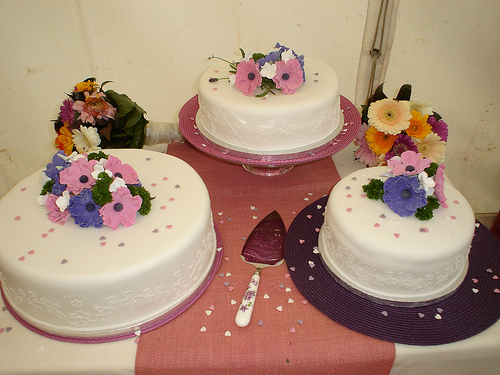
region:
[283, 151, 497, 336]
A cake on a purple place mat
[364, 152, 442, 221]
Icing flowers on a cake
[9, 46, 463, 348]
Three white cakes on a table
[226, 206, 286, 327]
A small spatula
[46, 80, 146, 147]
A bouquet of fake flowers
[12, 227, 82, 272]
Heart shaped sprinkles on a cake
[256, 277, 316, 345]
Sprinkles on the tablecloth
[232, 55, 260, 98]
A pink flower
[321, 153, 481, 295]
A white cake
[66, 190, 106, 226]
A purple flower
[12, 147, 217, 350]
A white cake with flowers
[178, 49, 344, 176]
A cake on a pink plate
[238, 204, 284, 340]
A cake server on a table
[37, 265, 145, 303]
The edge of a white cake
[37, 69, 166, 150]
A bouquet of flowers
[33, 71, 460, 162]
Two bouquets of flowers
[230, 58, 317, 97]
Two pink flowers on a cake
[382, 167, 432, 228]
A purple flower on a cake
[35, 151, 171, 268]
A bunch of flowers on a cake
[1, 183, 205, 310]
this is a cake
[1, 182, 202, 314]
the cake is white in color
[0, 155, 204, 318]
the cake is large in size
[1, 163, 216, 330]
the cake is creamy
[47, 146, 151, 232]
the cream is flower like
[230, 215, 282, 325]
this is a spoon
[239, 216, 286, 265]
the spoon is creamy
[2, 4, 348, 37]
the wall is white in color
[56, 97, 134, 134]
these are flowers beside the cake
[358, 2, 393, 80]
this is a rope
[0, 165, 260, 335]
Cake on the table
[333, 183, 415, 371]
Cake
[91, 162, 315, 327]
Confetti on the table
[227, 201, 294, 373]
Cake cutter on the table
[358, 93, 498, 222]
Flowers next to the cake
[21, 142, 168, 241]
Flowers made out of icing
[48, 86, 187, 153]
Bouquet of flowers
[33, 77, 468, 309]
Three cakes on the table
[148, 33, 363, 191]
A cake on a platter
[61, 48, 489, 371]
A celebration with cake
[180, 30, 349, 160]
A decorated cake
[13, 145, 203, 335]
A cake decorated with blue and pink flowers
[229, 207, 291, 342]
A cake serving spoon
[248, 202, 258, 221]
Confetti decorates this cake table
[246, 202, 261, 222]
confetti is often used to decorated party tables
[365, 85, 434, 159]
colorful flowers accent this party table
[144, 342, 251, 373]
A pink table runner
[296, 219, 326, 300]
A cake plate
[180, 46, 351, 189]
This cake is on a pedestal cake stand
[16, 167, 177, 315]
The cake is decorated in white fondant